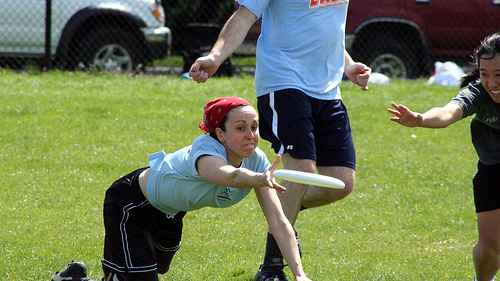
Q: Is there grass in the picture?
A: Yes, there is grass.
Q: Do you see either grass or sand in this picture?
A: Yes, there is grass.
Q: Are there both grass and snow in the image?
A: No, there is grass but no snow.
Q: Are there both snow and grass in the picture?
A: No, there is grass but no snow.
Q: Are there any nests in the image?
A: No, there are no nests.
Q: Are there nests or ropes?
A: No, there are no nests or ropes.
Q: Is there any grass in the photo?
A: Yes, there is grass.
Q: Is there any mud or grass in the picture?
A: Yes, there is grass.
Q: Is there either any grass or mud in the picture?
A: Yes, there is grass.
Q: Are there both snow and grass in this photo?
A: No, there is grass but no snow.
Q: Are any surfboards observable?
A: No, there are no surfboards.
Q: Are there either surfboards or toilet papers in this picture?
A: No, there are no surfboards or toilet papers.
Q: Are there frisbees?
A: Yes, there is a frisbee.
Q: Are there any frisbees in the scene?
A: Yes, there is a frisbee.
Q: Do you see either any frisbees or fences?
A: Yes, there is a frisbee.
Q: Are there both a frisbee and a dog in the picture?
A: No, there is a frisbee but no dogs.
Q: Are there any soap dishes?
A: No, there are no soap dishes.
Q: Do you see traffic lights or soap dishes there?
A: No, there are no soap dishes or traffic lights.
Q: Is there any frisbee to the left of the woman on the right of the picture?
A: Yes, there is a frisbee to the left of the woman.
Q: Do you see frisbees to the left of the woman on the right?
A: Yes, there is a frisbee to the left of the woman.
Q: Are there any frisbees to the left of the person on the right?
A: Yes, there is a frisbee to the left of the woman.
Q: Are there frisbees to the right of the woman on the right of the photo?
A: No, the frisbee is to the left of the woman.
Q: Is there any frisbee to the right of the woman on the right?
A: No, the frisbee is to the left of the woman.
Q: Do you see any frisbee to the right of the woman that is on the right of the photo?
A: No, the frisbee is to the left of the woman.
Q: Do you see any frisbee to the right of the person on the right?
A: No, the frisbee is to the left of the woman.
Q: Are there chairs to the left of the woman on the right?
A: No, there is a frisbee to the left of the woman.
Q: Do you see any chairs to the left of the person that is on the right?
A: No, there is a frisbee to the left of the woman.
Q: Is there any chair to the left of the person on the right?
A: No, there is a frisbee to the left of the woman.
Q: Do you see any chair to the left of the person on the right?
A: No, there is a frisbee to the left of the woman.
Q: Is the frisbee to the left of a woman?
A: Yes, the frisbee is to the left of a woman.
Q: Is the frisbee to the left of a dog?
A: No, the frisbee is to the left of a woman.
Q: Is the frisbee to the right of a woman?
A: No, the frisbee is to the left of a woman.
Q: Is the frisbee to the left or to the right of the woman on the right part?
A: The frisbee is to the left of the woman.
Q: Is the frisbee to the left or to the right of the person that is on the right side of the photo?
A: The frisbee is to the left of the woman.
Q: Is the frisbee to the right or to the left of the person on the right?
A: The frisbee is to the left of the woman.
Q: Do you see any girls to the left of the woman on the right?
A: Yes, there is a girl to the left of the woman.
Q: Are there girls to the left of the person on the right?
A: Yes, there is a girl to the left of the woman.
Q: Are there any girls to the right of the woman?
A: No, the girl is to the left of the woman.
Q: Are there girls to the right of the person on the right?
A: No, the girl is to the left of the woman.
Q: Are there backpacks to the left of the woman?
A: No, there is a girl to the left of the woman.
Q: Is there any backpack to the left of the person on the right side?
A: No, there is a girl to the left of the woman.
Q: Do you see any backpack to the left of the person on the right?
A: No, there is a girl to the left of the woman.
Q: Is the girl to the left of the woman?
A: Yes, the girl is to the left of the woman.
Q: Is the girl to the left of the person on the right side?
A: Yes, the girl is to the left of the woman.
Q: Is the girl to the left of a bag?
A: No, the girl is to the left of the woman.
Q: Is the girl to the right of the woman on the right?
A: No, the girl is to the left of the woman.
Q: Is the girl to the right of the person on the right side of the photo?
A: No, the girl is to the left of the woman.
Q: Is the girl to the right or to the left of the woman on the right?
A: The girl is to the left of the woman.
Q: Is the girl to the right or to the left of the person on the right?
A: The girl is to the left of the woman.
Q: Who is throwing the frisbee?
A: The girl is throwing the frisbee.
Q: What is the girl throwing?
A: The girl is throwing the frisbee.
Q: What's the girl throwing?
A: The girl is throwing the frisbee.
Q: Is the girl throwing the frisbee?
A: Yes, the girl is throwing the frisbee.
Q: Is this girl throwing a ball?
A: No, the girl is throwing the frisbee.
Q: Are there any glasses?
A: No, there are no glasses.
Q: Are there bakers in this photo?
A: No, there are no bakers.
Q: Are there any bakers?
A: No, there are no bakers.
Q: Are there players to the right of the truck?
A: Yes, there is a player to the right of the truck.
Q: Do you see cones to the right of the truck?
A: No, there is a player to the right of the truck.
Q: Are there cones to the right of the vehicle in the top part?
A: No, there is a player to the right of the truck.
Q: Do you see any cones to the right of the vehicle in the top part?
A: No, there is a player to the right of the truck.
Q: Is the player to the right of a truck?
A: Yes, the player is to the right of a truck.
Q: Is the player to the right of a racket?
A: No, the player is to the right of a truck.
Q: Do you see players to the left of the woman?
A: Yes, there is a player to the left of the woman.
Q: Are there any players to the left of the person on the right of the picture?
A: Yes, there is a player to the left of the woman.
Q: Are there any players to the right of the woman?
A: No, the player is to the left of the woman.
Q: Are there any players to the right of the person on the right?
A: No, the player is to the left of the woman.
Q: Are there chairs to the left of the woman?
A: No, there is a player to the left of the woman.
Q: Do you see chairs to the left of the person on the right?
A: No, there is a player to the left of the woman.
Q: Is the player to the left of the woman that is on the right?
A: Yes, the player is to the left of the woman.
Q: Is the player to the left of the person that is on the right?
A: Yes, the player is to the left of the woman.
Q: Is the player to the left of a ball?
A: No, the player is to the left of the woman.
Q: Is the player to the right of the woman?
A: No, the player is to the left of the woman.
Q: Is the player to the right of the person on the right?
A: No, the player is to the left of the woman.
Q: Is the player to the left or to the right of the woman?
A: The player is to the left of the woman.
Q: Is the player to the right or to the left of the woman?
A: The player is to the left of the woman.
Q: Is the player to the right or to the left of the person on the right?
A: The player is to the left of the woman.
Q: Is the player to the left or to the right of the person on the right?
A: The player is to the left of the woman.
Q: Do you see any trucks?
A: Yes, there is a truck.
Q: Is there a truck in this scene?
A: Yes, there is a truck.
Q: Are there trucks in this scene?
A: Yes, there is a truck.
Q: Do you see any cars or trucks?
A: Yes, there is a truck.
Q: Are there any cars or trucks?
A: Yes, there is a truck.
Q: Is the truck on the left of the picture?
A: Yes, the truck is on the left of the image.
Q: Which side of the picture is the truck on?
A: The truck is on the left of the image.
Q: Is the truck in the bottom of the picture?
A: No, the truck is in the top of the image.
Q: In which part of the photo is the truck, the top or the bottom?
A: The truck is in the top of the image.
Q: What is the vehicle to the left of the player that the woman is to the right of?
A: The vehicle is a truck.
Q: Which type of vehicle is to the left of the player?
A: The vehicle is a truck.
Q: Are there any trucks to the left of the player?
A: Yes, there is a truck to the left of the player.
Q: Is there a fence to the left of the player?
A: No, there is a truck to the left of the player.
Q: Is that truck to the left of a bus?
A: No, the truck is to the left of a player.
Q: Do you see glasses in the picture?
A: No, there are no glasses.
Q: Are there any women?
A: Yes, there is a woman.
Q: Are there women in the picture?
A: Yes, there is a woman.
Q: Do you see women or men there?
A: Yes, there is a woman.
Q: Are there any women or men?
A: Yes, there is a woman.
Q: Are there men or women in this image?
A: Yes, there is a woman.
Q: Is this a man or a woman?
A: This is a woman.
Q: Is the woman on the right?
A: Yes, the woman is on the right of the image.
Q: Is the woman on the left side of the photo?
A: No, the woman is on the right of the image.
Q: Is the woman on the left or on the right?
A: The woman is on the right of the image.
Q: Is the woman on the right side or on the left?
A: The woman is on the right of the image.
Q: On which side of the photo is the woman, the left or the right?
A: The woman is on the right of the image.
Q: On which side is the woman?
A: The woman is on the right of the image.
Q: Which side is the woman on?
A: The woman is on the right of the image.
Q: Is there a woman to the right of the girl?
A: Yes, there is a woman to the right of the girl.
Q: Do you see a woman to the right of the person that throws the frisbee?
A: Yes, there is a woman to the right of the girl.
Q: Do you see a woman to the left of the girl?
A: No, the woman is to the right of the girl.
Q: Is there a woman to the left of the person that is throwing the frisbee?
A: No, the woman is to the right of the girl.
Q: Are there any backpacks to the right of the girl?
A: No, there is a woman to the right of the girl.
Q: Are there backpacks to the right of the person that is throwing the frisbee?
A: No, there is a woman to the right of the girl.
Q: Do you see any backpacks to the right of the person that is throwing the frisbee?
A: No, there is a woman to the right of the girl.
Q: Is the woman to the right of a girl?
A: Yes, the woman is to the right of a girl.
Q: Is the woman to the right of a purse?
A: No, the woman is to the right of a girl.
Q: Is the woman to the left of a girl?
A: No, the woman is to the right of a girl.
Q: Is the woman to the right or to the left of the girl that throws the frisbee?
A: The woman is to the right of the girl.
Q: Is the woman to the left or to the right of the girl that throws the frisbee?
A: The woman is to the right of the girl.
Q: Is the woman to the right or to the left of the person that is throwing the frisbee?
A: The woman is to the right of the girl.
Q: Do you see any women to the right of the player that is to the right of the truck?
A: Yes, there is a woman to the right of the player.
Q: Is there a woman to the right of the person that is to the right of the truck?
A: Yes, there is a woman to the right of the player.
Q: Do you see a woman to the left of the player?
A: No, the woman is to the right of the player.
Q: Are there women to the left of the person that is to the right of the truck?
A: No, the woman is to the right of the player.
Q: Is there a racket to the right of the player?
A: No, there is a woman to the right of the player.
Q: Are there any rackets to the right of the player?
A: No, there is a woman to the right of the player.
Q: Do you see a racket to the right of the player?
A: No, there is a woman to the right of the player.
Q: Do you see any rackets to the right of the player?
A: No, there is a woman to the right of the player.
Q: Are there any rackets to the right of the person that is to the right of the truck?
A: No, there is a woman to the right of the player.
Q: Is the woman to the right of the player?
A: Yes, the woman is to the right of the player.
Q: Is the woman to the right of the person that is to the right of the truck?
A: Yes, the woman is to the right of the player.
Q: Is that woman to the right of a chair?
A: No, the woman is to the right of the player.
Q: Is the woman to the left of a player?
A: No, the woman is to the right of a player.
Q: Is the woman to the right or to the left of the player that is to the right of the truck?
A: The woman is to the right of the player.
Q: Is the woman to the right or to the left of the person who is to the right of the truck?
A: The woman is to the right of the player.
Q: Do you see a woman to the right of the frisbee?
A: Yes, there is a woman to the right of the frisbee.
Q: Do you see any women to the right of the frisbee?
A: Yes, there is a woman to the right of the frisbee.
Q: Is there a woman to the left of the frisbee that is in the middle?
A: No, the woman is to the right of the frisbee.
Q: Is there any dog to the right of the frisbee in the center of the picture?
A: No, there is a woman to the right of the frisbee.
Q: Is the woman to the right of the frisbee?
A: Yes, the woman is to the right of the frisbee.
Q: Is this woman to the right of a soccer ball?
A: No, the woman is to the right of the frisbee.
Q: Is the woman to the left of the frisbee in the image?
A: No, the woman is to the right of the frisbee.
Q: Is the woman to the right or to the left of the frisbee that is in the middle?
A: The woman is to the right of the frisbee.